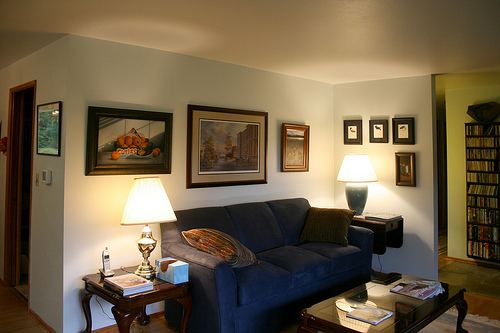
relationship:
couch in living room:
[160, 197, 375, 332] [5, 35, 497, 332]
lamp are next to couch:
[121, 178, 178, 225] [160, 197, 375, 332]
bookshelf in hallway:
[464, 122, 500, 261] [12, 36, 492, 326]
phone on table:
[101, 247, 111, 274] [78, 261, 205, 331]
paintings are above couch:
[83, 88, 313, 189] [167, 195, 377, 330]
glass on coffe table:
[302, 283, 443, 331] [283, 272, 463, 331]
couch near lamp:
[160, 197, 375, 332] [335, 154, 381, 214]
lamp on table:
[121, 178, 178, 225] [81, 256, 197, 332]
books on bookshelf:
[465, 121, 497, 258] [464, 122, 500, 261]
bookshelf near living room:
[464, 122, 500, 261] [5, 35, 497, 332]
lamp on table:
[121, 178, 178, 225] [78, 261, 205, 331]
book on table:
[103, 272, 154, 303] [78, 261, 205, 331]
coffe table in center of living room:
[298, 272, 469, 333] [5, 35, 497, 332]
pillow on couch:
[181, 228, 261, 268] [160, 197, 375, 332]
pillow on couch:
[300, 207, 356, 246] [160, 197, 375, 332]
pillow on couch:
[299, 203, 352, 249] [160, 197, 375, 332]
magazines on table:
[395, 271, 448, 306] [307, 266, 475, 332]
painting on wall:
[81, 100, 176, 173] [74, 41, 337, 330]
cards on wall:
[342, 113, 363, 146] [329, 70, 442, 296]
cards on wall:
[366, 117, 386, 146] [329, 70, 442, 296]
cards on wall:
[395, 117, 419, 147] [329, 70, 442, 296]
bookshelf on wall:
[460, 114, 498, 266] [440, 70, 497, 270]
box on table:
[154, 255, 190, 288] [81, 256, 197, 332]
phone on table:
[99, 244, 116, 277] [78, 259, 199, 326]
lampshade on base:
[118, 173, 184, 231] [133, 226, 162, 276]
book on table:
[107, 267, 156, 304] [78, 259, 199, 326]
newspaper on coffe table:
[392, 272, 451, 298] [298, 272, 469, 333]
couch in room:
[167, 195, 377, 330] [4, 2, 498, 331]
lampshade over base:
[336, 151, 381, 182] [339, 185, 370, 218]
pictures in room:
[75, 95, 328, 196] [4, 2, 498, 331]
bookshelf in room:
[464, 122, 500, 261] [7, 31, 498, 328]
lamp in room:
[120, 173, 177, 278] [4, 2, 498, 331]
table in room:
[74, 255, 209, 332] [4, 2, 498, 331]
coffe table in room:
[298, 272, 469, 333] [4, 2, 498, 331]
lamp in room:
[335, 151, 375, 221] [4, 2, 498, 331]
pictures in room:
[334, 114, 437, 148] [4, 2, 498, 331]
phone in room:
[101, 247, 111, 274] [4, 2, 498, 331]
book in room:
[103, 267, 162, 302] [4, 2, 498, 331]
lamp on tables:
[121, 178, 178, 225] [73, 206, 432, 326]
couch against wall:
[167, 195, 377, 330] [74, 41, 337, 330]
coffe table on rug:
[298, 272, 469, 333] [413, 300, 497, 330]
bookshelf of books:
[464, 122, 500, 261] [465, 128, 494, 268]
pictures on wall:
[32, 95, 422, 198] [31, 38, 443, 330]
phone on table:
[101, 247, 111, 274] [75, 265, 195, 330]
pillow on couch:
[174, 223, 259, 271] [167, 195, 377, 330]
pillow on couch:
[300, 207, 356, 246] [167, 195, 377, 330]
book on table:
[101, 267, 154, 300] [75, 265, 195, 330]